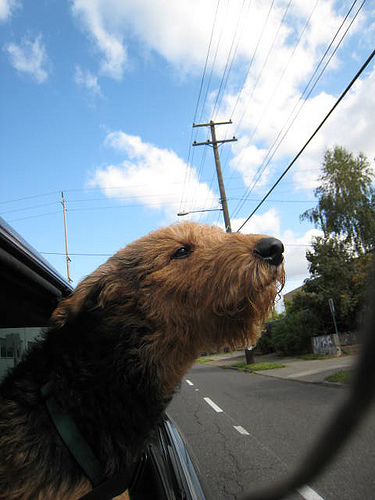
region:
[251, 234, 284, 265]
nose of a dog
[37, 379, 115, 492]
collar of a dog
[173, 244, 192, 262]
eye of a dog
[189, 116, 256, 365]
tall wooden power line post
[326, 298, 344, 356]
backside of a sign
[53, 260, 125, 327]
ear of a dog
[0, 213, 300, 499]
dog is sticking it's head out of a car window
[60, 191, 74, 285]
a wooden post for power lines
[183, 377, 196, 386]
white line on concrete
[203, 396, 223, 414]
white line on concrete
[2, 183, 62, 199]
high voltage power line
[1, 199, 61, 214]
high voltage power line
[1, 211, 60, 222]
high voltage power line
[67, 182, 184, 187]
high voltage power line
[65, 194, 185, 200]
high voltage power line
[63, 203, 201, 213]
high voltage power line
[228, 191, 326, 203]
high voltage power line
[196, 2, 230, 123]
high voltage power line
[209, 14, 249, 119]
high voltage power line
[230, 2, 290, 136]
high voltage power line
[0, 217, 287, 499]
dog with its head out of a window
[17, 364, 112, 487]
collar on a dog's neck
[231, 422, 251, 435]
thick white dash on a street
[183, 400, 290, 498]
long crack on a street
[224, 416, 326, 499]
two white dash lines on a street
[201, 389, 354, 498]
three thick white dash lines on a street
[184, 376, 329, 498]
four dash lines on a street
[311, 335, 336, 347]
graffitti on a wall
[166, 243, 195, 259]
brown eye of a dog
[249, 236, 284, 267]
black nose of a dog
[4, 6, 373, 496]
a scene during the day time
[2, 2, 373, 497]
a scene on the street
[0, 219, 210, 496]
an open car window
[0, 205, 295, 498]
a brown dog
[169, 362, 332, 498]
white lines on street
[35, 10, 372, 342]
phone lines above the road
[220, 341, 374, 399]
a gray sidewalk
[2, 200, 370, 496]
The dog has his head out a car window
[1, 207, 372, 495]
The dog is smelling the air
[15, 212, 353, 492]
The dog is enjoying the ride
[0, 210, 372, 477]
The dog has lots of longhair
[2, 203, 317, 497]
The dog is looking for cats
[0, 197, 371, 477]
A dog is going for a ride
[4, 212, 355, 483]
A dog is inside a car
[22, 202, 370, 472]
The dog is enjoying the day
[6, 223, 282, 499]
A dog hanging out a car window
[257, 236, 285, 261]
A black nose on a dog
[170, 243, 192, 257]
A brown eye on a dog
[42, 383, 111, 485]
A collar on a dog's neck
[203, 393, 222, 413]
A white line on a road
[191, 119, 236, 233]
A telephone pole on a street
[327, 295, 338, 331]
A sign near a street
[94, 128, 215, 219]
A white cloud in a blue sky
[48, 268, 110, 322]
A furry ear on a dog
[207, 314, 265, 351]
Tan hair on a dog's chin